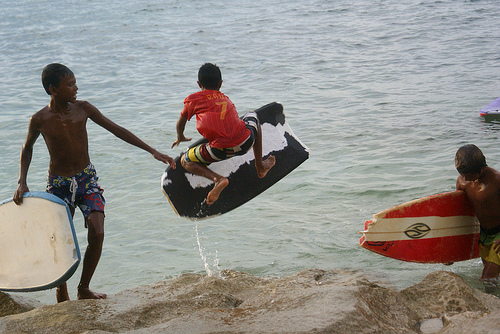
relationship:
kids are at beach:
[15, 63, 179, 300] [2, 4, 498, 332]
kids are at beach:
[177, 64, 276, 203] [2, 4, 498, 332]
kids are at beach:
[455, 144, 499, 277] [2, 4, 498, 332]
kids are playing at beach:
[15, 63, 179, 300] [2, 4, 498, 332]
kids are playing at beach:
[177, 64, 276, 203] [2, 4, 498, 332]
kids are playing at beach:
[455, 144, 499, 277] [2, 4, 498, 332]